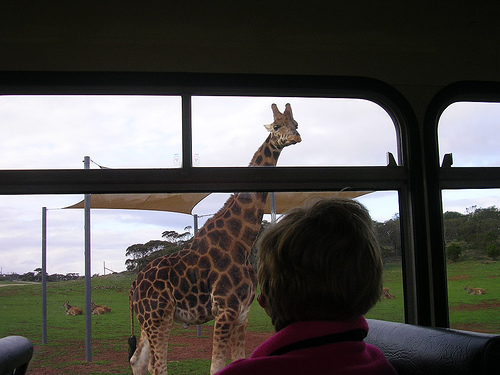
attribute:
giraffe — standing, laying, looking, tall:
[96, 99, 300, 375]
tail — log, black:
[125, 333, 140, 361]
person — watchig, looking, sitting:
[233, 194, 396, 372]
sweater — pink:
[216, 318, 392, 374]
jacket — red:
[186, 333, 421, 373]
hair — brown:
[285, 231, 343, 275]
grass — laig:
[25, 310, 123, 343]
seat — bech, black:
[389, 325, 499, 374]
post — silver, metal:
[81, 207, 102, 355]